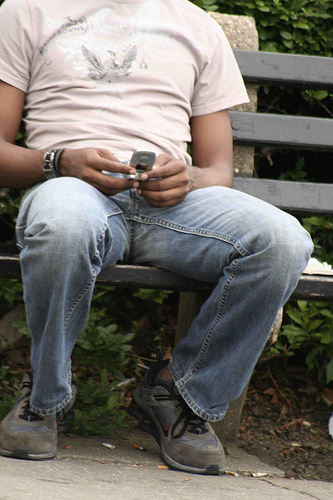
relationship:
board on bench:
[1, 241, 330, 299] [0, 14, 330, 439]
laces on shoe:
[153, 392, 209, 440] [114, 351, 239, 478]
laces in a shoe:
[11, 408, 44, 424] [0, 368, 72, 458]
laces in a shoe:
[155, 387, 222, 446] [118, 350, 233, 476]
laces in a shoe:
[153, 392, 209, 440] [0, 366, 232, 475]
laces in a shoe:
[18, 380, 67, 423] [0, 368, 72, 458]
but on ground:
[221, 466, 241, 475] [0, 427, 320, 497]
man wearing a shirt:
[0, 9, 320, 473] [4, 4, 274, 171]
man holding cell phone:
[0, 9, 320, 473] [125, 151, 156, 181]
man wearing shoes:
[0, 9, 320, 473] [0, 351, 229, 481]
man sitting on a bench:
[0, 9, 320, 473] [0, 14, 330, 439]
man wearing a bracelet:
[0, 9, 320, 473] [37, 147, 69, 176]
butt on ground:
[100, 434, 172, 472] [2, 429, 198, 498]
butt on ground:
[52, 438, 76, 452] [0, 427, 320, 497]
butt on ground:
[100, 440, 116, 449] [0, 427, 320, 497]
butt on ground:
[98, 440, 122, 450] [0, 427, 320, 497]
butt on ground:
[101, 443, 116, 450] [0, 427, 320, 497]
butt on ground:
[220, 467, 272, 479] [9, 437, 322, 498]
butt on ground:
[154, 461, 275, 479] [0, 427, 320, 497]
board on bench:
[293, 273, 322, 295] [212, 43, 319, 302]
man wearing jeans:
[0, 0, 314, 477] [15, 156, 317, 427]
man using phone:
[0, 0, 314, 477] [121, 147, 154, 183]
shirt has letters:
[10, 4, 247, 182] [41, 15, 82, 44]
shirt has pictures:
[10, 4, 247, 182] [70, 32, 156, 91]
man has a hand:
[0, 0, 314, 477] [39, 138, 137, 189]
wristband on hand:
[34, 144, 67, 177] [39, 138, 137, 189]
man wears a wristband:
[0, 0, 314, 477] [34, 144, 67, 177]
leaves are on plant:
[293, 29, 317, 38] [240, 0, 332, 190]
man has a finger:
[0, 0, 314, 477] [93, 154, 136, 175]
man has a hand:
[0, 0, 314, 477] [140, 151, 193, 211]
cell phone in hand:
[125, 151, 156, 181] [140, 151, 193, 211]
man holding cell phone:
[0, 0, 314, 477] [125, 151, 156, 181]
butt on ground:
[101, 442, 116, 449] [71, 418, 313, 497]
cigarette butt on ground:
[132, 440, 147, 455] [5, 417, 328, 493]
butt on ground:
[158, 464, 170, 469] [29, 404, 315, 498]